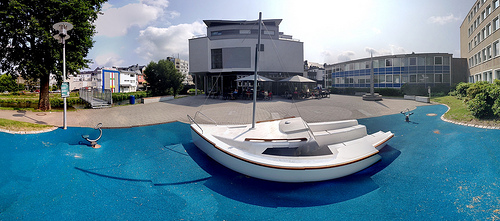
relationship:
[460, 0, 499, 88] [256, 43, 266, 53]
building has window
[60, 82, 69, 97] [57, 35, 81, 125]
green sign on metal pole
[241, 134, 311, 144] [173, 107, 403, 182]
railing on boat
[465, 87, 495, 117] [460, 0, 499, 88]
green bush next to building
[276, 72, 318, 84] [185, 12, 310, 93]
parasol in front of a building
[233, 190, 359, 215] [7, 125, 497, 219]
shadow in water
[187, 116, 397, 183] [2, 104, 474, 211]
boat in creek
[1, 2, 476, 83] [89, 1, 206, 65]
sky with white clouds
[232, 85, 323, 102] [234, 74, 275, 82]
seating has parasol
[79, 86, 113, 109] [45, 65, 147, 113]
bridge with fence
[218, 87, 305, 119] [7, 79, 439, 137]
shadows on pavement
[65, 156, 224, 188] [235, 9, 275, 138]
reflection of pole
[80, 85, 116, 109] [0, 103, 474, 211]
bridge over creek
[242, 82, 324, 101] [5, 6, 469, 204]
people sitting outside